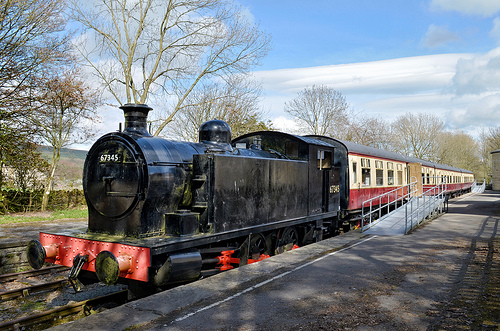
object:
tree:
[60, 0, 272, 139]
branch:
[67, 9, 248, 99]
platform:
[42, 183, 498, 327]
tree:
[34, 68, 91, 210]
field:
[1, 185, 82, 226]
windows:
[420, 168, 427, 186]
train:
[42, 116, 474, 276]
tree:
[282, 83, 356, 144]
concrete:
[118, 193, 500, 327]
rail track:
[0, 226, 147, 325]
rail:
[403, 173, 468, 236]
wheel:
[249, 237, 267, 258]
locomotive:
[26, 109, 347, 291]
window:
[361, 157, 373, 188]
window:
[374, 160, 385, 189]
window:
[387, 160, 395, 186]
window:
[397, 164, 405, 185]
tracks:
[437, 205, 500, 317]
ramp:
[360, 175, 448, 236]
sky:
[1, 0, 499, 151]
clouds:
[0, 1, 499, 150]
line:
[186, 237, 376, 314]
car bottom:
[347, 186, 409, 208]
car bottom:
[422, 183, 479, 199]